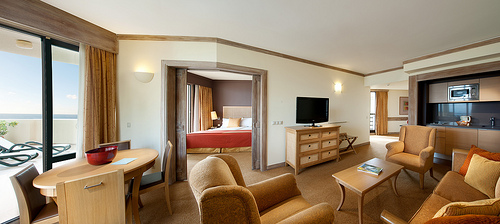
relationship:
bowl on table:
[87, 143, 130, 162] [42, 157, 148, 198]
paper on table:
[111, 155, 140, 168] [42, 157, 148, 198]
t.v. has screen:
[291, 93, 334, 125] [304, 104, 328, 117]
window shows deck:
[1, 32, 89, 172] [7, 119, 100, 164]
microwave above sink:
[448, 85, 485, 107] [435, 119, 469, 136]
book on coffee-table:
[360, 163, 380, 175] [341, 158, 406, 223]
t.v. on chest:
[291, 93, 334, 125] [292, 127, 337, 172]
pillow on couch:
[464, 149, 475, 158] [407, 148, 500, 224]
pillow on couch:
[467, 163, 496, 192] [407, 148, 500, 224]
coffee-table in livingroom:
[341, 158, 406, 223] [211, 80, 467, 206]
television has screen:
[291, 93, 334, 125] [304, 104, 328, 117]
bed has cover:
[205, 109, 251, 149] [195, 127, 248, 149]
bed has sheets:
[205, 109, 251, 149] [221, 132, 262, 149]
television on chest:
[291, 93, 334, 125] [292, 127, 337, 172]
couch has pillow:
[441, 159, 484, 215] [467, 155, 497, 192]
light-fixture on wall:
[325, 75, 355, 101] [261, 59, 393, 113]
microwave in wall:
[448, 85, 485, 107] [427, 72, 487, 109]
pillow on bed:
[221, 114, 256, 132] [205, 109, 251, 149]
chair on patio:
[6, 138, 66, 144] [10, 102, 94, 195]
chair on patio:
[5, 151, 30, 173] [10, 102, 94, 195]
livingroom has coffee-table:
[211, 80, 467, 206] [341, 158, 406, 223]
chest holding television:
[292, 127, 337, 172] [291, 93, 334, 125]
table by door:
[42, 157, 148, 198] [43, 43, 88, 161]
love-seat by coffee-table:
[441, 159, 484, 215] [341, 172, 406, 194]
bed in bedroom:
[205, 109, 251, 149] [183, 77, 260, 156]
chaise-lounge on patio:
[3, 138, 64, 166] [10, 102, 94, 195]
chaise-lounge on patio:
[6, 151, 34, 163] [10, 102, 94, 195]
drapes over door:
[89, 49, 120, 147] [43, 43, 88, 161]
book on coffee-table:
[359, 166, 381, 177] [341, 172, 406, 194]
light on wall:
[129, 65, 159, 83] [118, 52, 172, 139]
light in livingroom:
[129, 65, 159, 83] [211, 80, 467, 206]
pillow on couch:
[464, 149, 475, 158] [441, 159, 484, 215]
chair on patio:
[3, 138, 64, 166] [10, 102, 94, 195]